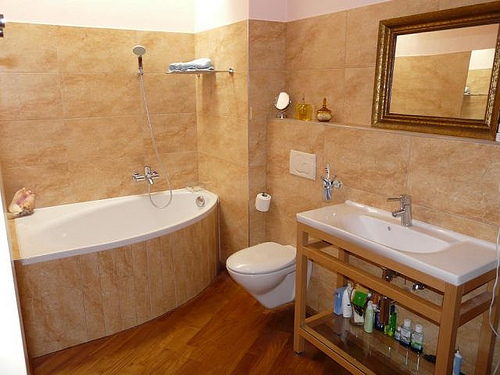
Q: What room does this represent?
A: It represents the bathroom.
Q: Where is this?
A: This is at the bathroom.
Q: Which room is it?
A: It is a bathroom.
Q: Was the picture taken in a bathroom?
A: Yes, it was taken in a bathroom.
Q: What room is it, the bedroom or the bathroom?
A: It is the bathroom.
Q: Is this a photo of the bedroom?
A: No, the picture is showing the bathroom.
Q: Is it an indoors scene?
A: Yes, it is indoors.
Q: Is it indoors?
A: Yes, it is indoors.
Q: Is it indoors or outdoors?
A: It is indoors.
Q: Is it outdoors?
A: No, it is indoors.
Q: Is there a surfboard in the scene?
A: No, there are no surfboards.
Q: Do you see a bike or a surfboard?
A: No, there are no surfboards or bikes.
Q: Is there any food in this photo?
A: No, there is no food.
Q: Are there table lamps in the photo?
A: No, there are no table lamps.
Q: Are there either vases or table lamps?
A: No, there are no table lamps or vases.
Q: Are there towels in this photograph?
A: Yes, there is a towel.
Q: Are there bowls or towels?
A: Yes, there is a towel.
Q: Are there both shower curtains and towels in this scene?
A: No, there is a towel but no shower curtains.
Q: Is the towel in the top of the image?
A: Yes, the towel is in the top of the image.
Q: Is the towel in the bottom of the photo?
A: No, the towel is in the top of the image.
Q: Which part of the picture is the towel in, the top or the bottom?
A: The towel is in the top of the image.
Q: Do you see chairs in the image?
A: No, there are no chairs.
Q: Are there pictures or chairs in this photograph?
A: No, there are no chairs or pictures.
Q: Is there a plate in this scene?
A: No, there are no plates.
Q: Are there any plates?
A: No, there are no plates.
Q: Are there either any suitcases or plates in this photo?
A: No, there are no plates or suitcases.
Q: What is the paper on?
A: The paper is on the wall.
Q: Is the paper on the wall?
A: Yes, the paper is on the wall.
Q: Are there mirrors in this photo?
A: Yes, there is a mirror.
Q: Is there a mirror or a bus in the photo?
A: Yes, there is a mirror.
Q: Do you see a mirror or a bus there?
A: Yes, there is a mirror.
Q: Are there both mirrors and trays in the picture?
A: No, there is a mirror but no trays.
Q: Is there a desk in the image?
A: No, there are no desks.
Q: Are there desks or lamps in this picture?
A: No, there are no desks or lamps.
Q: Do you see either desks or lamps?
A: No, there are no desks or lamps.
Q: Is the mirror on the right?
A: Yes, the mirror is on the right of the image.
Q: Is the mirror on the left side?
A: No, the mirror is on the right of the image.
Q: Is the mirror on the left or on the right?
A: The mirror is on the right of the image.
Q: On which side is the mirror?
A: The mirror is on the right of the image.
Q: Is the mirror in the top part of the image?
A: Yes, the mirror is in the top of the image.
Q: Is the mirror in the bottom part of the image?
A: No, the mirror is in the top of the image.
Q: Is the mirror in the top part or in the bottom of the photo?
A: The mirror is in the top of the image.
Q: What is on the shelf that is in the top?
A: The mirror is on the shelf.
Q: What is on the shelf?
A: The mirror is on the shelf.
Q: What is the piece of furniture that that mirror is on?
A: The piece of furniture is a shelf.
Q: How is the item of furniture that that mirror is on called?
A: The piece of furniture is a shelf.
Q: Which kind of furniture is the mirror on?
A: The mirror is on the shelf.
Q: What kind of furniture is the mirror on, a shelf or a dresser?
A: The mirror is on a shelf.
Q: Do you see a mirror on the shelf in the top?
A: Yes, there is a mirror on the shelf.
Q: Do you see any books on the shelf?
A: No, there is a mirror on the shelf.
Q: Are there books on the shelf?
A: No, there is a mirror on the shelf.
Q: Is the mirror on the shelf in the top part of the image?
A: Yes, the mirror is on the shelf.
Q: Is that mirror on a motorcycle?
A: No, the mirror is on the shelf.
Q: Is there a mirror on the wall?
A: Yes, there is a mirror on the wall.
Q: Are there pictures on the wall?
A: No, there is a mirror on the wall.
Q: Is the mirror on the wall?
A: Yes, the mirror is on the wall.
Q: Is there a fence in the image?
A: No, there are no fences.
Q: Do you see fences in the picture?
A: No, there are no fences.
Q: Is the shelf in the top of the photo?
A: Yes, the shelf is in the top of the image.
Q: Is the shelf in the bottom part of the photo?
A: No, the shelf is in the top of the image.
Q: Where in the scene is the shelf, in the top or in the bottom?
A: The shelf is in the top of the image.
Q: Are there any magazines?
A: No, there are no magazines.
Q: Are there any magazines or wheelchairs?
A: No, there are no magazines or wheelchairs.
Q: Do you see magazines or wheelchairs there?
A: No, there are no magazines or wheelchairs.